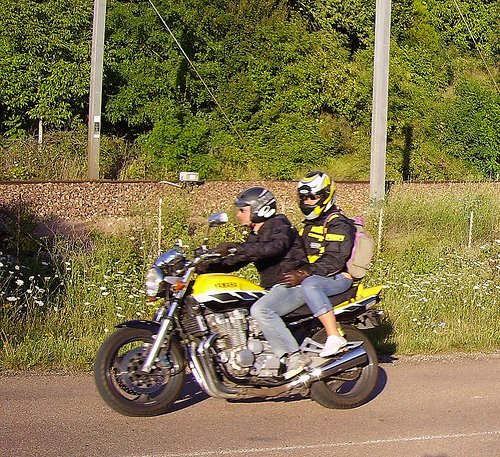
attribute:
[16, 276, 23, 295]
white flower — small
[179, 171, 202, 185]
electrical box — metal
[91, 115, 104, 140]
white sign — black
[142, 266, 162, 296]
headlight — shiny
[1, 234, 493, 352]
flowers — white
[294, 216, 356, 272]
jacket — yellow, black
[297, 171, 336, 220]
motorcycle helmet — black, yellow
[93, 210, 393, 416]
motorcycle — yellow, black, yellow and black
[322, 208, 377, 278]
backpack — tan, pink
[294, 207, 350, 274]
jacket — yellow, black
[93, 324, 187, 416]
wheel — black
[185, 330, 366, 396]
muffler — long, chrome